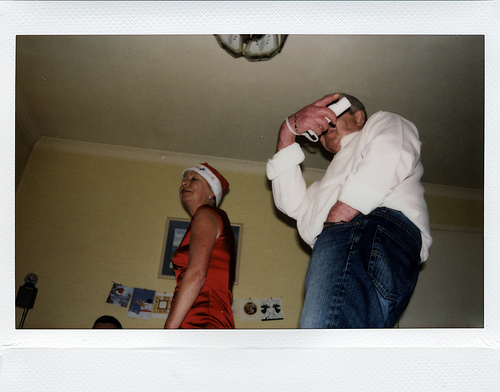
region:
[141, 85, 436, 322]
a man and woman playing a game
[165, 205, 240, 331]
a red and black dress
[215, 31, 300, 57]
a light on the ceiling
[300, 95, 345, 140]
a game control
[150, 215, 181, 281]
a picture on a wall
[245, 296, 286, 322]
paper hanging on a wall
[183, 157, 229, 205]
a Christmas hat on a head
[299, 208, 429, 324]
a pair of blue jeans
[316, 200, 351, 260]
a hand in a pocket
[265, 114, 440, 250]
a white shirt on a man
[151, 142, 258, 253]
a woman wearing a santa hat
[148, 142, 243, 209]
a red and white santa hat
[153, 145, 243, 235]
a woman wearing earrings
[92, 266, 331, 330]
christmas cards on the wall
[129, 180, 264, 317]
a picture frame on the wall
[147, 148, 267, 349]
a woman wearing a red dress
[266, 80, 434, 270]
a man holding a white controller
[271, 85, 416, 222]
a man wearing a white shirt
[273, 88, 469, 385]
a man wearing blue jeans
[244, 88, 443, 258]
a man wearing a long sleeve shirt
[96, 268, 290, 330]
pictures on the wall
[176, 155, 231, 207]
hat on woman's head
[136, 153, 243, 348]
woman standing in Christmas hat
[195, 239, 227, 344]
wrinkles in the woman's dress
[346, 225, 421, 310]
back pocket of man's pants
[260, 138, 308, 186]
cuff of the man's shirt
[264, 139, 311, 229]
sleeve of the man's shirt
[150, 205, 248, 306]
picture behind the woman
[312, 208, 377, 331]
seam on the man's jeans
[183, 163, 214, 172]
writing on the woman's hat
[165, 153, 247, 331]
woman with a santa hat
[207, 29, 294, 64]
light attached to the ceiling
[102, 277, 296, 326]
photos clipped to a string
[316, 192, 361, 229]
hand in man's pocket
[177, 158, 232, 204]
red and white santa hat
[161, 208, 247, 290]
picture hanging on the wall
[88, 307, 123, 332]
visible portion of the top of someone's head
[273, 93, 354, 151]
white wii remote in a man's hand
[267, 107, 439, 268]
man's white long sleeved shirt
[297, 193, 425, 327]
man's blue jeans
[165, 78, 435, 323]
two people playing a game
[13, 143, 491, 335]
yellow wall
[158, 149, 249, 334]
woman in a santa outfit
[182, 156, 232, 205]
santa clause hat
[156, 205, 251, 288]
framed picture on the wall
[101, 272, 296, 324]
string of pictures on the wall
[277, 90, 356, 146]
wii remote in a man's hand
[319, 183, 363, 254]
man's hand in his pocket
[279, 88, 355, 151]
man's hand obscuring his face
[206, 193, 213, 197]
earring in a woman's left ear